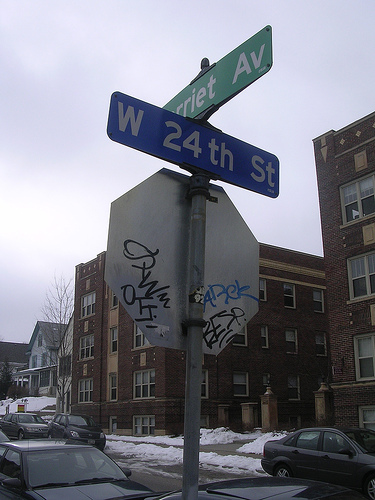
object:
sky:
[23, 92, 78, 160]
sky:
[18, 78, 81, 169]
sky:
[36, 114, 94, 175]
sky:
[11, 116, 74, 185]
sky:
[25, 99, 90, 229]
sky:
[306, 40, 359, 87]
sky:
[70, 39, 149, 75]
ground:
[117, 429, 246, 489]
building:
[73, 242, 327, 454]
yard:
[10, 389, 59, 416]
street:
[5, 408, 298, 497]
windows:
[80, 380, 96, 402]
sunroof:
[206, 466, 326, 498]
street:
[4, 413, 331, 498]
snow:
[97, 422, 287, 473]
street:
[24, 409, 276, 490]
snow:
[95, 410, 293, 476]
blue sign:
[107, 90, 280, 199]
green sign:
[160, 23, 272, 110]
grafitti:
[119, 233, 171, 308]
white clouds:
[12, 14, 54, 93]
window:
[320, 432, 348, 453]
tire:
[274, 465, 289, 481]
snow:
[107, 437, 256, 475]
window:
[346, 200, 360, 224]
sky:
[3, 3, 374, 122]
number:
[163, 120, 183, 149]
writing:
[204, 301, 248, 352]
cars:
[46, 411, 104, 447]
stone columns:
[315, 388, 327, 427]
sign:
[17, 405, 28, 413]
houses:
[0, 317, 77, 429]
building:
[310, 112, 374, 445]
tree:
[31, 266, 86, 415]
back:
[102, 172, 263, 350]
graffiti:
[205, 276, 256, 309]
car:
[261, 427, 372, 498]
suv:
[4, 414, 47, 438]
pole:
[184, 196, 208, 495]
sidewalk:
[102, 427, 265, 465]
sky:
[3, 4, 374, 154]